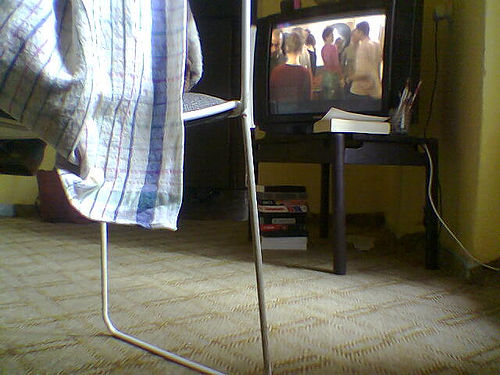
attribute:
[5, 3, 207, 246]
towel — white, blue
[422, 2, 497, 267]
wall — yellow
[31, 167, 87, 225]
purse — pink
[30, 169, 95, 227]
laptop — small, red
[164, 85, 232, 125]
seat — grey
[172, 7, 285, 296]
chair — thin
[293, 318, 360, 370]
rug — tan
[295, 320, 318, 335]
line — yellow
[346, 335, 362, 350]
line — yellow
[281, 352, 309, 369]
line — yellow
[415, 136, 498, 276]
cord — white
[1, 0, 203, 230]
plaid cloth — white, blue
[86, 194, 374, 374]
fllor — tan, brown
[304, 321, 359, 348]
square — brown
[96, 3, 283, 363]
frame — white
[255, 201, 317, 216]
movie — vhs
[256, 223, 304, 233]
movie — vhs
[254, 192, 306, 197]
movie — vhs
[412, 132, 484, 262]
wire — white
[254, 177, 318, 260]
stack — books, small